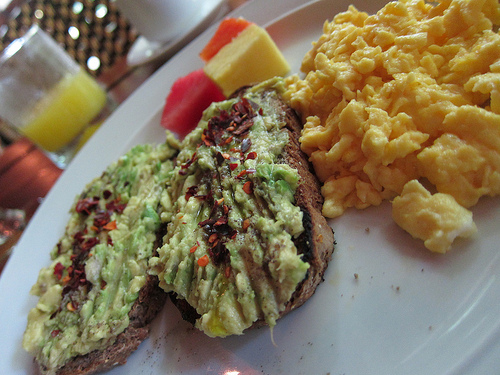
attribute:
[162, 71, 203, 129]
watermelon — small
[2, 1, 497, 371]
dish — large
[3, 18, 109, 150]
glass — small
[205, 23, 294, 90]
cheese — cube 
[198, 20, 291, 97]
pineapple — small, cubed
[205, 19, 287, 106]
melon — cubed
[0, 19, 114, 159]
glass — half full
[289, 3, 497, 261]
scrambled eggs — served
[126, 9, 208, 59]
cup — white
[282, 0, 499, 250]
eggs — scrambled 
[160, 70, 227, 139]
watermelon — chunk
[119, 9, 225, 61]
saucer — white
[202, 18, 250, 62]
orange slice — small